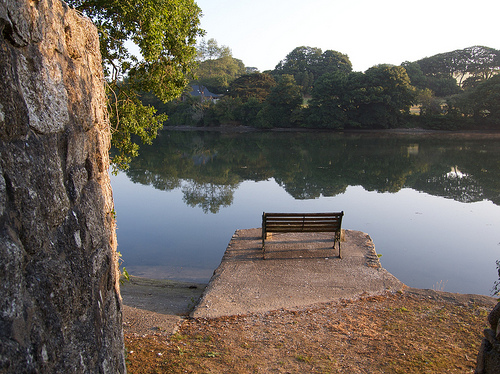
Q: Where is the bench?
A: Outcropping over water.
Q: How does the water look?
A: Green and calm.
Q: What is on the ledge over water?
A: Bench.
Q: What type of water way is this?
A: Lake.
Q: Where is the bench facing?
A: Trees across lake.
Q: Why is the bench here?
A: Scenic viewpoing.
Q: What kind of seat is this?
A: A bench.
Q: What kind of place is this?
A: A lake.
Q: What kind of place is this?
A: A lake surrounded by trees.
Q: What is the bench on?
A: A small concrete platform.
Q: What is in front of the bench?
A: A row of green trees.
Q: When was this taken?
A: During dusk or dawn.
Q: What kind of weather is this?
A: Clear with small clouds.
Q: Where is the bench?
A: On the concrete slab.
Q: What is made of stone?
A: The wall.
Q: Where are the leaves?
A: On the trees.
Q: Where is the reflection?
A: On the water.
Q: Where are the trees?
A: Along the shore.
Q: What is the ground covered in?
A: Dirt.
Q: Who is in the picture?
A: No one.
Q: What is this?
A: A lake scene.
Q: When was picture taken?
A: During daylight.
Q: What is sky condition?
A: Clear.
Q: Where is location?
A: By the dock.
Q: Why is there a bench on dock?
A: For leisure.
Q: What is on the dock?
A: A bench.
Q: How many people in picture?
A: None.